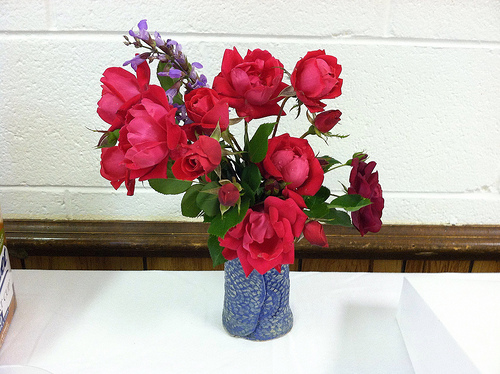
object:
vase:
[221, 257, 292, 341]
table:
[0, 268, 500, 374]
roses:
[97, 48, 386, 277]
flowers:
[121, 19, 210, 125]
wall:
[0, 0, 500, 229]